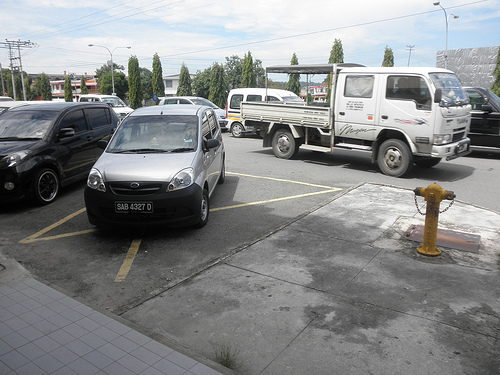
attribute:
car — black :
[2, 93, 119, 204]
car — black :
[6, 96, 117, 208]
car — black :
[6, 88, 111, 205]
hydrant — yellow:
[411, 185, 454, 258]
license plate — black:
[118, 202, 156, 214]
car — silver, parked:
[83, 103, 228, 231]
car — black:
[0, 105, 115, 212]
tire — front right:
[377, 136, 411, 179]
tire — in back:
[273, 127, 298, 160]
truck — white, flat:
[240, 66, 474, 181]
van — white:
[229, 87, 302, 141]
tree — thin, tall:
[153, 52, 167, 101]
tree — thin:
[124, 58, 145, 109]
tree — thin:
[177, 64, 195, 100]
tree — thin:
[209, 63, 227, 104]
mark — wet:
[282, 216, 384, 266]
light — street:
[83, 42, 126, 93]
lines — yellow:
[219, 167, 336, 217]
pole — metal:
[6, 48, 35, 99]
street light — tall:
[432, 2, 462, 68]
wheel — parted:
[268, 131, 306, 165]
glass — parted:
[118, 115, 200, 153]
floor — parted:
[246, 159, 338, 180]